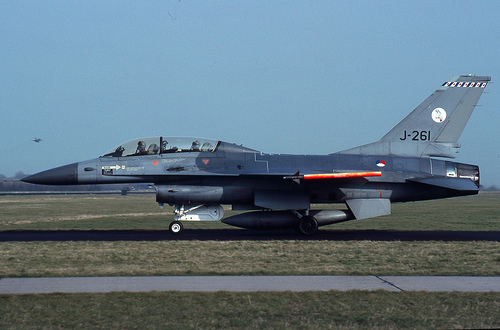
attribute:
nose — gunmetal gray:
[3, 156, 80, 193]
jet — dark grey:
[20, 74, 488, 237]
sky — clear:
[0, 1, 499, 188]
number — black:
[396, 128, 434, 143]